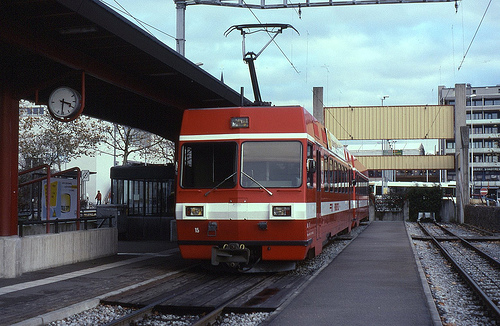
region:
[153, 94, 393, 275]
train on the track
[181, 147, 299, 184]
window on the train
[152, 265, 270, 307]
track train is on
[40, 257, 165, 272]
platform near the train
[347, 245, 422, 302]
pavement near the train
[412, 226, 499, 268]
tracks near the pavement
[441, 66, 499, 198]
building near the track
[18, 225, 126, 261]
concrete block near track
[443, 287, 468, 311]
rocks near the track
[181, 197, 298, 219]
lights on the train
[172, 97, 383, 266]
Red train on the tracks.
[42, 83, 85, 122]
Clock on the platform.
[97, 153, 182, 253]
Railing on the platform.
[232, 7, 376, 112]
Wires on top of the train.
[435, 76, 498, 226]
Building in the background.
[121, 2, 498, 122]
Cloudy skys in the background.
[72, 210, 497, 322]
Tracks on which the train runs.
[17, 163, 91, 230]
Advertising sign by the tracks.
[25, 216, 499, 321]
Rocks surrounding the tracks.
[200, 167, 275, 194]
Windshield wipers on the train.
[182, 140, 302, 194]
clear clean windshield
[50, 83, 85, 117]
a white clock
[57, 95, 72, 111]
black hands on the clock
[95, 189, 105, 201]
a person standing on the street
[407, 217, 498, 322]
empty railroad tracks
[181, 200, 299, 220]
headlights on the train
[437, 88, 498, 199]
building with many windows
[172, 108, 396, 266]
a red and white train on the tracks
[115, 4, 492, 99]
blue and white sky above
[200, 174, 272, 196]
windshield wipers on the train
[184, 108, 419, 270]
the train is red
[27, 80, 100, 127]
the clock is white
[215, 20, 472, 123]
there are clouds in the sky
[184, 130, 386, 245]
the train has two cars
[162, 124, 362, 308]
the train is on the tracks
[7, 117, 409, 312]
train at the station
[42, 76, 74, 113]
the clock dials are black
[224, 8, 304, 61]
metal poles up above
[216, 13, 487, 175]
electric wiring above the train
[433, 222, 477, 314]
gravel on the tracks